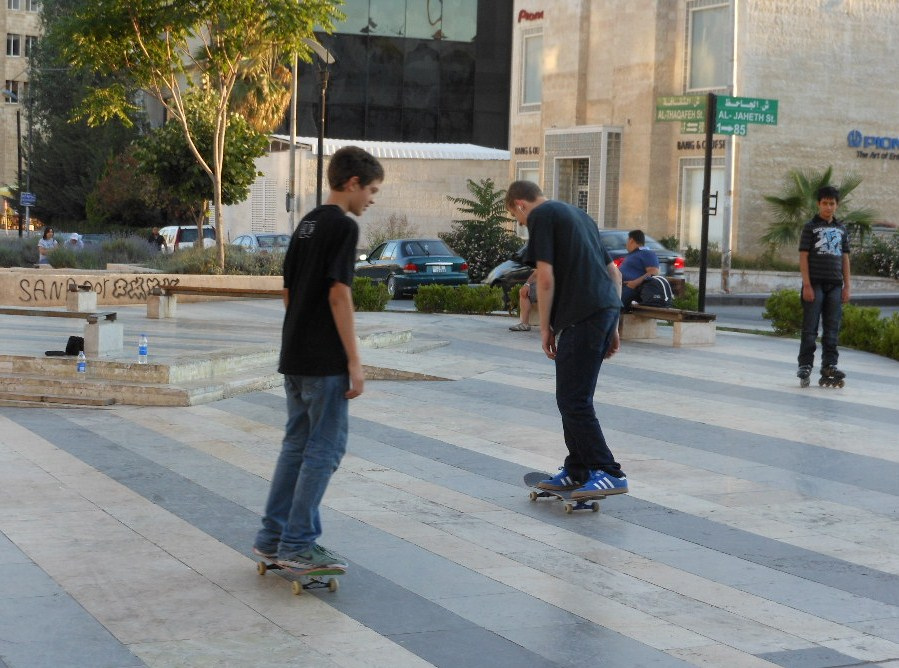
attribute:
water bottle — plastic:
[126, 317, 155, 359]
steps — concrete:
[28, 330, 322, 411]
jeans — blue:
[273, 363, 361, 565]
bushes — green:
[413, 268, 514, 317]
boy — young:
[489, 183, 636, 487]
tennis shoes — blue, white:
[547, 461, 622, 493]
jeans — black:
[557, 330, 625, 473]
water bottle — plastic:
[122, 327, 164, 362]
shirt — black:
[270, 206, 368, 366]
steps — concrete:
[2, 301, 345, 435]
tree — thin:
[70, 13, 324, 267]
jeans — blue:
[270, 366, 348, 565]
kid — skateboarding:
[250, 140, 385, 573]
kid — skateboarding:
[498, 173, 632, 498]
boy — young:
[259, 135, 396, 558]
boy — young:
[790, 174, 852, 373]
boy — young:
[244, 143, 405, 551]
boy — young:
[233, 134, 399, 545]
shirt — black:
[794, 210, 856, 308]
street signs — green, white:
[647, 83, 794, 132]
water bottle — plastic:
[137, 326, 158, 368]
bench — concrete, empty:
[3, 299, 132, 364]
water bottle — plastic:
[137, 331, 154, 370]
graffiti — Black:
[10, 268, 178, 297]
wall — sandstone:
[0, 269, 279, 311]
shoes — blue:
[540, 469, 626, 496]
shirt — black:
[279, 204, 357, 373]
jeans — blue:
[253, 369, 347, 558]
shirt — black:
[523, 202, 622, 322]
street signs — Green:
[654, 93, 776, 137]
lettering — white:
[660, 98, 767, 135]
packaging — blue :
[75, 361, 86, 372]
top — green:
[801, 219, 848, 284]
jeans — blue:
[257, 371, 351, 562]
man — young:
[505, 179, 627, 502]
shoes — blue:
[525, 469, 634, 503]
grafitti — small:
[11, 279, 176, 301]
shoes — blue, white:
[523, 472, 634, 503]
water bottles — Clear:
[73, 331, 153, 375]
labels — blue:
[77, 346, 147, 375]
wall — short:
[2, 266, 281, 308]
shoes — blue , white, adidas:
[526, 465, 625, 505]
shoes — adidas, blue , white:
[521, 472, 632, 499]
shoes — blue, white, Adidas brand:
[535, 462, 629, 504]